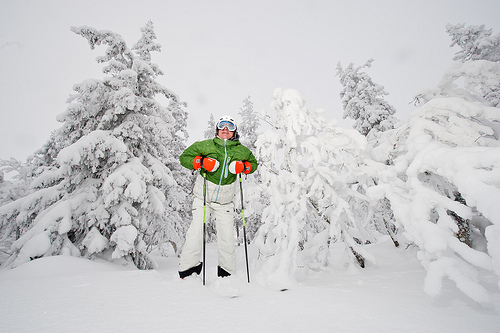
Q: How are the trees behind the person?
A: Covered with snow.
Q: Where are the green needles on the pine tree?
A: Covered with snow.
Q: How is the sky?
A: White with snow.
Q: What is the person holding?
A: Ski poles.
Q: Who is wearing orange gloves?
A: The skier.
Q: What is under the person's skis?
A: Snow.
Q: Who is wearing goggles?
A: The person on skis.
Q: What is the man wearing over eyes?
A: Goggles.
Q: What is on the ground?
A: Snow.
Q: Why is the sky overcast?
A: Cloudy.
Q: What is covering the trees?
A: Snow.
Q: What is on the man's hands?
A: Gloves.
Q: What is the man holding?
A: Poles.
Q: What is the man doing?
A: Skiing.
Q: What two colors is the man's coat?
A: Green and white.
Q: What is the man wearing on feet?
A: Boots.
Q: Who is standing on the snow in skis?
A: A man.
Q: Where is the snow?
A: On hill.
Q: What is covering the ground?
A: Snow.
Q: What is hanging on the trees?
A: Snow.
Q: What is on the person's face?
A: Goggles.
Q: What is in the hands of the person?
A: Ski poles.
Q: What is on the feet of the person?
A: Skis.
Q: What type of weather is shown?
A: Overcast and snowy.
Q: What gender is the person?
A: Male.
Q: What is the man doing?
A: Standing.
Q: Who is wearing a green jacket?
A: The skier.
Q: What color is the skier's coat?
A: Green and white.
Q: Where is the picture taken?
A: Mountain.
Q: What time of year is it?
A: Winter.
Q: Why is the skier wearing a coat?
A: Cold.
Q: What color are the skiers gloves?
A: Orange and white.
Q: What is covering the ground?
A: Snow.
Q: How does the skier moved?
A: With skis and poles.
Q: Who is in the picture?
A: A skiier.